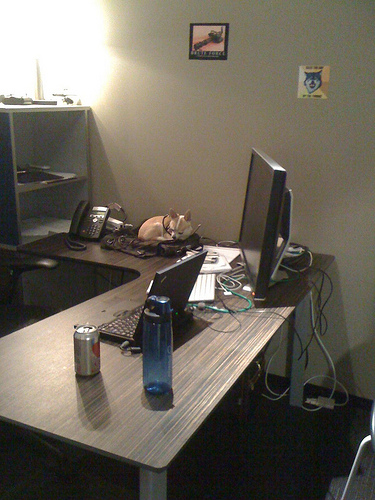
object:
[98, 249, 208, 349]
laptop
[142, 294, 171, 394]
bottle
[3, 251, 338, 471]
desk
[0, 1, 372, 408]
wall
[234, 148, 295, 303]
computer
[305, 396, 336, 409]
electronic plugs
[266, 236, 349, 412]
cord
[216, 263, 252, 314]
cord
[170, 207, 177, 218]
ear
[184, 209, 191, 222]
ear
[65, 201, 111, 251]
phone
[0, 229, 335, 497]
computer desk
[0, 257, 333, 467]
foreground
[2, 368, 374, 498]
floor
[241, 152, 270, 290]
screen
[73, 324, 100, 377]
can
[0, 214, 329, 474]
table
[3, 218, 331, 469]
wood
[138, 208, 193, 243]
dog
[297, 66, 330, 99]
picture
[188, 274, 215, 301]
keyboard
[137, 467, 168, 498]
leg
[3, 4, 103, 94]
sunlight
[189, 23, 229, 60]
picture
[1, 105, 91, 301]
cabinet